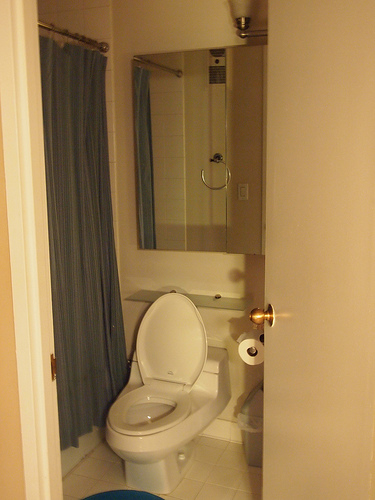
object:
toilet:
[104, 290, 231, 498]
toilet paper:
[236, 328, 264, 365]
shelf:
[124, 289, 248, 314]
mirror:
[134, 40, 266, 254]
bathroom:
[1, 0, 373, 497]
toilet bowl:
[127, 402, 174, 425]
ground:
[224, 124, 241, 151]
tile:
[62, 438, 264, 500]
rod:
[40, 19, 110, 56]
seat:
[108, 384, 190, 432]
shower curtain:
[39, 34, 130, 453]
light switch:
[237, 182, 248, 201]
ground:
[221, 71, 257, 109]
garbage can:
[238, 378, 264, 469]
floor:
[64, 429, 260, 498]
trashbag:
[241, 396, 277, 437]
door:
[262, 0, 375, 499]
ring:
[200, 152, 231, 191]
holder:
[246, 346, 258, 357]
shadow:
[228, 267, 246, 283]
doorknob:
[249, 303, 276, 328]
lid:
[136, 292, 208, 393]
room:
[35, 0, 263, 493]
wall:
[111, 2, 265, 431]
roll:
[236, 329, 265, 367]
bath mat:
[83, 487, 161, 499]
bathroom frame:
[3, 0, 63, 499]